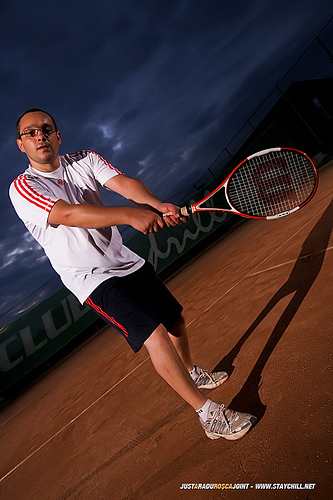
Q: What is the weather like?
A: It is stormy.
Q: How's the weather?
A: It is stormy.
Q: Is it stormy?
A: Yes, it is stormy.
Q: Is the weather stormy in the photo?
A: Yes, it is stormy.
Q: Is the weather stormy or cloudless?
A: It is stormy.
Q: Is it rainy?
A: No, it is stormy.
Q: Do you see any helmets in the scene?
A: No, there are no helmets.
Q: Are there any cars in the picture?
A: No, there are no cars.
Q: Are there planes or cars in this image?
A: No, there are no cars or planes.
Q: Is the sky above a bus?
A: No, the sky is above the man.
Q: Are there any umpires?
A: No, there are no umpires.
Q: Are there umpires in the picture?
A: No, there are no umpires.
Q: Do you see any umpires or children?
A: No, there are no umpires or children.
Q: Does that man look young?
A: Yes, the man is young.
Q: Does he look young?
A: Yes, the man is young.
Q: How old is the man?
A: The man is young.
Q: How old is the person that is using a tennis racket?
A: The man is young.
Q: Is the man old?
A: No, the man is young.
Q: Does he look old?
A: No, the man is young.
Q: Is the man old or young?
A: The man is young.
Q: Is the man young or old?
A: The man is young.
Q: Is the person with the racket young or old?
A: The man is young.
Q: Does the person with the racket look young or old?
A: The man is young.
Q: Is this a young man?
A: Yes, this is a young man.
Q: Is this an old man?
A: No, this is a young man.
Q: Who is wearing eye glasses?
A: The man is wearing eye glasses.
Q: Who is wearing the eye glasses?
A: The man is wearing eye glasses.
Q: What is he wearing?
A: The man is wearing eye glasses.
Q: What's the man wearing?
A: The man is wearing eye glasses.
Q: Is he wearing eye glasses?
A: Yes, the man is wearing eye glasses.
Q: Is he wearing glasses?
A: No, the man is wearing eye glasses.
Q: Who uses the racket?
A: The man uses the racket.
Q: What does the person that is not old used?
A: The man uses a racket.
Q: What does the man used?
A: The man uses a racket.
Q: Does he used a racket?
A: Yes, the man uses a racket.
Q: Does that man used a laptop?
A: No, the man uses a racket.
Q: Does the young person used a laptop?
A: No, the man uses a racket.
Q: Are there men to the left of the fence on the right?
A: Yes, there is a man to the left of the fence.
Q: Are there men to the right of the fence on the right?
A: No, the man is to the left of the fence.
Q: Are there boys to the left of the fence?
A: No, there is a man to the left of the fence.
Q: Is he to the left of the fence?
A: Yes, the man is to the left of the fence.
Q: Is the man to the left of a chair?
A: No, the man is to the left of the fence.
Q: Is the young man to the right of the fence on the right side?
A: No, the man is to the left of the fence.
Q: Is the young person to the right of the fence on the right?
A: No, the man is to the left of the fence.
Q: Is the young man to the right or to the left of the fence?
A: The man is to the left of the fence.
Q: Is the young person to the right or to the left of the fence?
A: The man is to the left of the fence.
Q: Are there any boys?
A: No, there are no boys.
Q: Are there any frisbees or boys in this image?
A: No, there are no boys or frisbees.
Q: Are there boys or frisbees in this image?
A: No, there are no boys or frisbees.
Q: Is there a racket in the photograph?
A: Yes, there is a racket.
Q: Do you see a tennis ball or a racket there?
A: Yes, there is a racket.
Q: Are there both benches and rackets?
A: No, there is a racket but no benches.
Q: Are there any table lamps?
A: No, there are no table lamps.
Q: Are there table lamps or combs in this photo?
A: No, there are no table lamps or combs.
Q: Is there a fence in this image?
A: Yes, there is a fence.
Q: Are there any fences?
A: Yes, there is a fence.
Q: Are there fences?
A: Yes, there is a fence.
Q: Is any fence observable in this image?
A: Yes, there is a fence.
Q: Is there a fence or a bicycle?
A: Yes, there is a fence.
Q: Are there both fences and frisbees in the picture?
A: No, there is a fence but no frisbees.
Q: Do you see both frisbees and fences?
A: No, there is a fence but no frisbees.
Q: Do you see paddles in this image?
A: No, there are no paddles.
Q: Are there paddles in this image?
A: No, there are no paddles.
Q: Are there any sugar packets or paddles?
A: No, there are no paddles or sugar packets.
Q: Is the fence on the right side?
A: Yes, the fence is on the right of the image.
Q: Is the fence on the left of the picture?
A: No, the fence is on the right of the image.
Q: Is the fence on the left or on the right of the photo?
A: The fence is on the right of the image.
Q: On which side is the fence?
A: The fence is on the right of the image.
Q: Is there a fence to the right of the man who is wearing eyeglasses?
A: Yes, there is a fence to the right of the man.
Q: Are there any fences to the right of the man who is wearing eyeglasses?
A: Yes, there is a fence to the right of the man.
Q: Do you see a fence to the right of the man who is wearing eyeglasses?
A: Yes, there is a fence to the right of the man.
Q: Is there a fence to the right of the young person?
A: Yes, there is a fence to the right of the man.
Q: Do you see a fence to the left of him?
A: No, the fence is to the right of the man.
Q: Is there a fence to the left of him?
A: No, the fence is to the right of the man.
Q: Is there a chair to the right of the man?
A: No, there is a fence to the right of the man.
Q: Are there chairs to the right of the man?
A: No, there is a fence to the right of the man.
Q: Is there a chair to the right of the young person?
A: No, there is a fence to the right of the man.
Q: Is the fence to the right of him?
A: Yes, the fence is to the right of the man.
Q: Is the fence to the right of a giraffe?
A: No, the fence is to the right of the man.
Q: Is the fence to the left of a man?
A: No, the fence is to the right of a man.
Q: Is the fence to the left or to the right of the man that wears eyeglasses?
A: The fence is to the right of the man.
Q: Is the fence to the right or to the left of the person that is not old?
A: The fence is to the right of the man.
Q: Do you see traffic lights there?
A: No, there are no traffic lights.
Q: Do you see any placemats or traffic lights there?
A: No, there are no traffic lights or placemats.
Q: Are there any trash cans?
A: No, there are no trash cans.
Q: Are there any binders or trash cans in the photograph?
A: No, there are no trash cans or binders.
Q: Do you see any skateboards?
A: No, there are no skateboards.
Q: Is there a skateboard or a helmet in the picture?
A: No, there are no skateboards or helmets.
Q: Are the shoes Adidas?
A: Yes, the shoes are adidas.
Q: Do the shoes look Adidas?
A: Yes, the shoes are adidas.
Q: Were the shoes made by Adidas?
A: Yes, the shoes were made by adidas.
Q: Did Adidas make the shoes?
A: Yes, the shoes were made by adidas.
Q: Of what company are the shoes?
A: The shoes are adidas.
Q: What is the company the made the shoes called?
A: The company is adidas.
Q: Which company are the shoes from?
A: The shoes are from adidas.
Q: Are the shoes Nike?
A: No, the shoes are adidas.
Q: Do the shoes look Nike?
A: No, the shoes are adidas.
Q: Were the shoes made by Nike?
A: No, the shoes were made by adidas.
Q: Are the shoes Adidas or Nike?
A: The shoes are adidas.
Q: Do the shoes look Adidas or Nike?
A: The shoes are adidas.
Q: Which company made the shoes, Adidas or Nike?
A: The shoes were made adidas.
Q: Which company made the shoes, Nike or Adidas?
A: The shoes were made adidas.